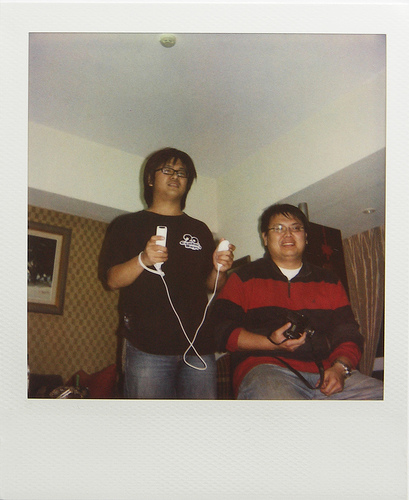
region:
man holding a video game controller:
[99, 147, 233, 398]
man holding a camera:
[217, 202, 381, 398]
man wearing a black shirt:
[95, 146, 226, 397]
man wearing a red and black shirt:
[209, 201, 383, 396]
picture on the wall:
[27, 222, 76, 317]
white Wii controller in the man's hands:
[139, 225, 229, 375]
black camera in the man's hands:
[269, 310, 325, 390]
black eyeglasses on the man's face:
[144, 166, 193, 180]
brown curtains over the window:
[342, 226, 380, 382]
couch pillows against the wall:
[26, 364, 123, 397]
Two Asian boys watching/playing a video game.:
[36, 42, 377, 391]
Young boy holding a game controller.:
[111, 145, 236, 330]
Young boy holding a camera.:
[244, 192, 342, 377]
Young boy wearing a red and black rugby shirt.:
[213, 201, 360, 375]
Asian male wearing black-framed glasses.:
[254, 199, 319, 267]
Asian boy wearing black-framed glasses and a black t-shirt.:
[104, 140, 226, 333]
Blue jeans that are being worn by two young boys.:
[114, 325, 378, 398]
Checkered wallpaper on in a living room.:
[33, 212, 124, 372]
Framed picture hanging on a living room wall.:
[13, 221, 69, 337]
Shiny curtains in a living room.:
[324, 212, 375, 372]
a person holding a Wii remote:
[106, 155, 230, 319]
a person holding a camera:
[243, 244, 359, 381]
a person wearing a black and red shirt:
[227, 233, 367, 379]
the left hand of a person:
[321, 355, 351, 398]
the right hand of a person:
[262, 323, 305, 353]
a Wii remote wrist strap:
[134, 243, 175, 281]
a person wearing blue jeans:
[119, 344, 219, 397]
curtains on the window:
[348, 222, 381, 369]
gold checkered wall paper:
[66, 301, 113, 344]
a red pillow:
[69, 365, 118, 399]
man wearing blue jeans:
[101, 147, 220, 399]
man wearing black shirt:
[98, 150, 227, 400]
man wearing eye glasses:
[111, 145, 224, 397]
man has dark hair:
[106, 150, 224, 397]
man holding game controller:
[105, 146, 225, 394]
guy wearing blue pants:
[212, 203, 382, 399]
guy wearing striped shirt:
[216, 201, 380, 396]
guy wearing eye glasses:
[220, 207, 378, 400]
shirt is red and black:
[212, 259, 360, 380]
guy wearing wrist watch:
[224, 205, 386, 400]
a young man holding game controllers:
[97, 138, 235, 347]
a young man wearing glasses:
[146, 147, 201, 193]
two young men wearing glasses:
[115, 146, 316, 269]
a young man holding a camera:
[261, 303, 320, 362]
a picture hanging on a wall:
[34, 217, 77, 336]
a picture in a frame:
[33, 217, 83, 323]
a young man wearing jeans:
[118, 355, 209, 395]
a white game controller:
[143, 223, 173, 286]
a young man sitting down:
[226, 193, 353, 400]